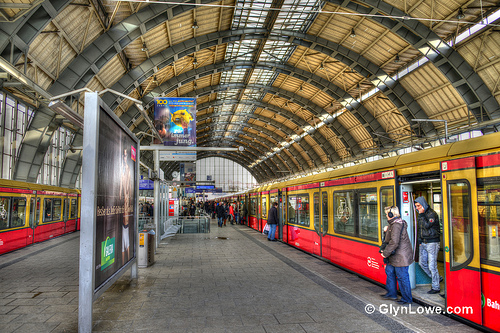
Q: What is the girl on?
A: Surfboard.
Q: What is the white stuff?
A: Foam.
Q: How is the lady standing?
A: Upright.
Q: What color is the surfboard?
A: Blue.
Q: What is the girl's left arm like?
A: Raised.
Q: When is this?
A: Morning.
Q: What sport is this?
A: Surfing.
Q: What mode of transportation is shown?
A: A train.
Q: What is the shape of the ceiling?
A: An arch.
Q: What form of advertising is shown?
A: A billboard.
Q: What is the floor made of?
A: Cement tile.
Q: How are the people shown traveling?
A: By train.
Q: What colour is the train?
A: Red and yellow.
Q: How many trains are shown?
A: 2 (two).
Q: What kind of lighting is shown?
A: Indirect sunlight.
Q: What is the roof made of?
A: Glass and metal.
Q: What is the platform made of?
A: Bricks.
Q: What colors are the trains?
A: Red and yellow.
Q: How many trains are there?
A: Two.